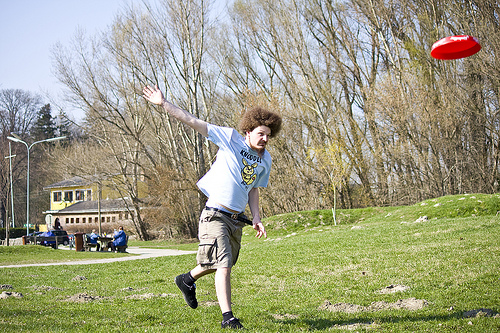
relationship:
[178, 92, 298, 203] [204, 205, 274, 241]
man wearing belt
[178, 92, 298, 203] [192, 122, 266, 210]
man wearing shirt